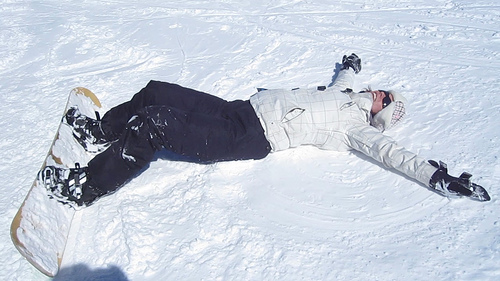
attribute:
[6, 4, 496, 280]
snow — white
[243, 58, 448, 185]
coat — white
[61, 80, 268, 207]
pants — black